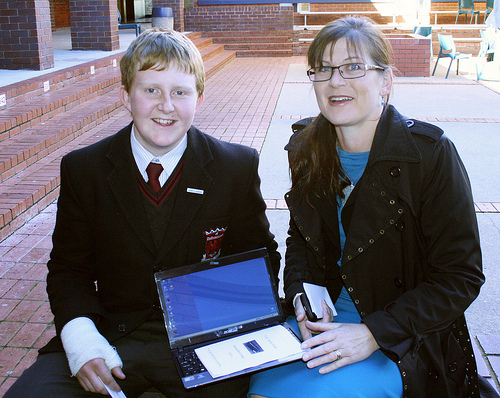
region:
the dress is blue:
[316, 140, 373, 385]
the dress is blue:
[246, 134, 423, 396]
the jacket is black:
[273, 105, 450, 376]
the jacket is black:
[33, 115, 295, 363]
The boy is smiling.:
[103, 6, 219, 166]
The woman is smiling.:
[288, 13, 399, 175]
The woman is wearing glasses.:
[283, 3, 412, 161]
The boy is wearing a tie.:
[97, 23, 218, 220]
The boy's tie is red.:
[108, 23, 208, 220]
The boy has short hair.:
[104, 14, 220, 196]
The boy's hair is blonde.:
[96, 15, 226, 168]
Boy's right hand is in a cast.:
[38, 19, 223, 396]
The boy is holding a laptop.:
[37, 19, 311, 396]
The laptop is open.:
[133, 234, 316, 394]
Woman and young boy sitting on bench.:
[18, 15, 496, 395]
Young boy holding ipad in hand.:
[149, 245, 313, 391]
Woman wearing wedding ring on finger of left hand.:
[330, 346, 351, 361]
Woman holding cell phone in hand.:
[297, 288, 318, 327]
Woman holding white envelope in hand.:
[301, 276, 343, 320]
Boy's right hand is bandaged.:
[57, 313, 129, 393]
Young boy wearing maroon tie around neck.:
[139, 155, 171, 198]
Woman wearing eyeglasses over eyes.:
[305, 53, 393, 85]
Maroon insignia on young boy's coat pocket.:
[193, 222, 231, 261]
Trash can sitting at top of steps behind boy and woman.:
[148, 4, 183, 36]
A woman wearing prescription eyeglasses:
[305, 14, 394, 126]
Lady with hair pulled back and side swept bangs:
[305, 16, 395, 127]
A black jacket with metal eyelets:
[281, 104, 485, 397]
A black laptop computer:
[152, 246, 309, 391]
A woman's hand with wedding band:
[298, 319, 380, 375]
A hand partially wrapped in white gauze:
[58, 314, 126, 396]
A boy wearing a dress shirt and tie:
[116, 26, 206, 193]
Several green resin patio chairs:
[412, 0, 497, 82]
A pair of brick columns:
[1, 1, 121, 71]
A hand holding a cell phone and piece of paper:
[291, 279, 337, 341]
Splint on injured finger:
[87, 371, 132, 396]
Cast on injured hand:
[56, 311, 129, 388]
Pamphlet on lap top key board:
[188, 315, 310, 385]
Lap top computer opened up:
[146, 245, 306, 390]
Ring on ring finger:
[330, 345, 355, 362]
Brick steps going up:
[1, 0, 233, 233]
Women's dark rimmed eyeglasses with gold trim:
[300, 60, 382, 86]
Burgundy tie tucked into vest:
[139, 153, 165, 203]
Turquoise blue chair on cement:
[421, 27, 483, 87]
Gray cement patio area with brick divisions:
[243, 35, 495, 330]